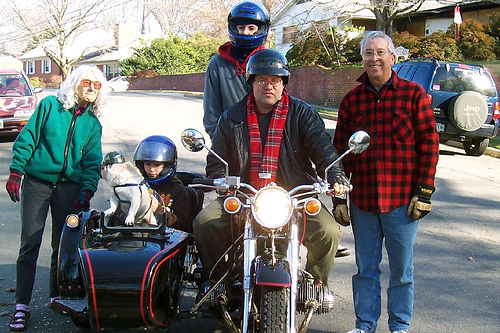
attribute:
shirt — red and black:
[335, 66, 434, 207]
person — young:
[181, 2, 287, 138]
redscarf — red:
[234, 97, 296, 185]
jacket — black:
[176, 86, 368, 258]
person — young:
[103, 132, 198, 233]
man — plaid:
[185, 51, 356, 311]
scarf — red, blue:
[235, 87, 295, 188]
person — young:
[132, 140, 194, 235]